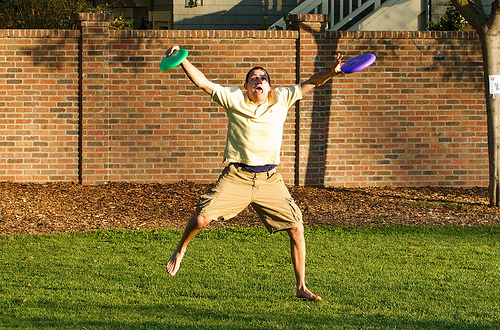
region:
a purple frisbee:
[342, 50, 377, 75]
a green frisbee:
[156, 47, 188, 72]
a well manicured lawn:
[64, 294, 239, 322]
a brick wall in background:
[1, 13, 495, 188]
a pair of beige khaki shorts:
[192, 165, 303, 235]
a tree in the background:
[0, 1, 125, 29]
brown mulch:
[34, 196, 145, 214]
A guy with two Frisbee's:
[162, 40, 377, 304]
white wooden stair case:
[264, 0, 429, 27]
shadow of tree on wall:
[17, 20, 165, 75]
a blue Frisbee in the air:
[338, 50, 380, 76]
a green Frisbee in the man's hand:
[156, 45, 191, 73]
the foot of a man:
[292, 285, 324, 302]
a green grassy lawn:
[1, 222, 498, 328]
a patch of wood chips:
[1, 180, 499, 234]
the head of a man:
[241, 65, 274, 105]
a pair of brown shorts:
[192, 162, 308, 237]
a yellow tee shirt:
[207, 82, 306, 167]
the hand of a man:
[162, 42, 182, 56]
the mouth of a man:
[251, 84, 266, 95]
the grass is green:
[77, 253, 440, 323]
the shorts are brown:
[198, 171, 323, 233]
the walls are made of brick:
[46, 101, 171, 165]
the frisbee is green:
[153, 36, 209, 85]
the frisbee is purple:
[338, 41, 396, 89]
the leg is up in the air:
[134, 163, 239, 295]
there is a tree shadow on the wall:
[296, 42, 336, 169]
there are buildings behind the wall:
[30, 8, 440, 30]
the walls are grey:
[163, 11, 263, 21]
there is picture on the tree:
[481, 75, 499, 93]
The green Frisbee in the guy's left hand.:
[152, 36, 191, 75]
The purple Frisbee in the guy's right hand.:
[339, 54, 381, 71]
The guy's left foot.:
[167, 248, 189, 282]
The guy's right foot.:
[297, 281, 320, 303]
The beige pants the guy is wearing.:
[189, 161, 313, 234]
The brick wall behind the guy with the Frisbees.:
[2, 47, 495, 186]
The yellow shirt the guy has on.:
[219, 87, 302, 163]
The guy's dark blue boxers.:
[236, 162, 278, 172]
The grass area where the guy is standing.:
[136, 245, 373, 317]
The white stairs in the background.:
[252, 0, 402, 28]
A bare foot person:
[135, 38, 437, 310]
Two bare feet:
[157, 242, 350, 307]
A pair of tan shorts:
[166, 162, 334, 241]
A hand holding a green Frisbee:
[144, 37, 198, 81]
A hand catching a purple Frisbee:
[324, 56, 396, 90]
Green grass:
[343, 239, 440, 288]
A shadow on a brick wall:
[282, 36, 378, 176]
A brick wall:
[112, 95, 183, 159]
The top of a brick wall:
[119, 30, 255, 46]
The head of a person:
[236, 60, 289, 111]